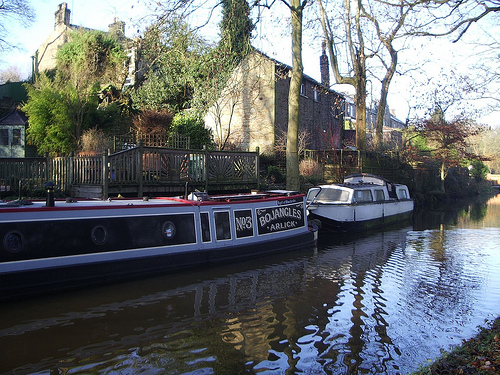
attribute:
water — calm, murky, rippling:
[2, 180, 497, 372]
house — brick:
[205, 35, 355, 157]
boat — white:
[304, 163, 419, 236]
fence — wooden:
[55, 151, 253, 185]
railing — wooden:
[4, 145, 261, 188]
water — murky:
[302, 253, 484, 374]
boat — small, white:
[303, 178, 418, 224]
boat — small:
[300, 171, 414, 233]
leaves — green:
[132, 37, 205, 111]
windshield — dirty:
[305, 189, 349, 204]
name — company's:
[226, 202, 306, 235]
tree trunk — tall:
[284, 2, 301, 193]